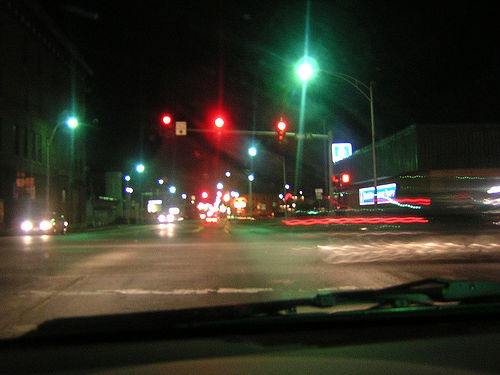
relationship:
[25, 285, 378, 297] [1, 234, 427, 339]
traffic line in intersection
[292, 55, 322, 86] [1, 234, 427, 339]
street light over intersection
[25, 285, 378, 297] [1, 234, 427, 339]
traffic line on intersection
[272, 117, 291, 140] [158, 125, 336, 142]
light on crossbar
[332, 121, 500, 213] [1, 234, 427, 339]
building near intersection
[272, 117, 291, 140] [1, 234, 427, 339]
light over intersection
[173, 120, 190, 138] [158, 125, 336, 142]
traffic sign on crossbar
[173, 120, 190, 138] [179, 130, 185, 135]
traffic sign has circle